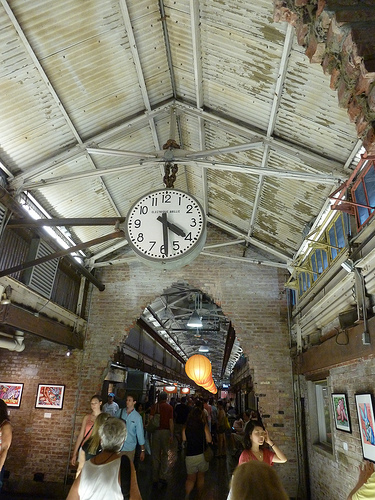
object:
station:
[0, 0, 375, 500]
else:
[67, 393, 332, 479]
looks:
[0, 0, 375, 500]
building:
[0, 0, 375, 499]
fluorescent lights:
[186, 313, 203, 328]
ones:
[184, 354, 212, 382]